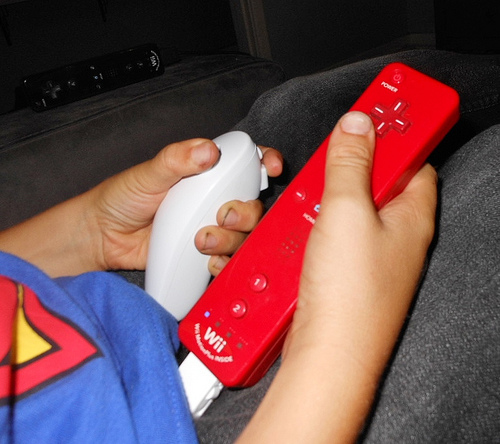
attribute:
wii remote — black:
[16, 35, 165, 115]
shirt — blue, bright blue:
[1, 251, 217, 443]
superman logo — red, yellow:
[1, 278, 108, 403]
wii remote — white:
[144, 133, 268, 313]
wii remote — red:
[177, 63, 459, 391]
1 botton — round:
[245, 271, 269, 297]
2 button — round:
[226, 300, 243, 318]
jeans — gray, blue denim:
[224, 40, 498, 432]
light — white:
[205, 309, 213, 318]